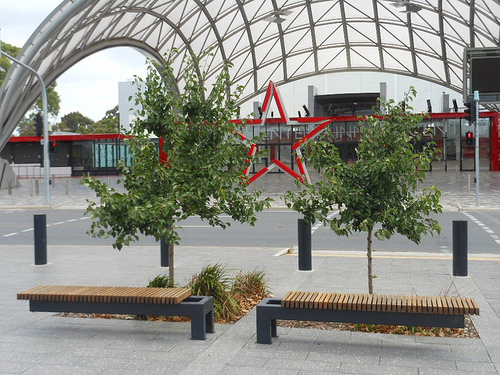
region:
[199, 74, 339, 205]
wire star in air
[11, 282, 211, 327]
bench on the ground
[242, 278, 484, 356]
bench on the ground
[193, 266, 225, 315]
grass in the flower bed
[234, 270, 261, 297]
grass in the flower bed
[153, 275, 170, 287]
grass in the flower bed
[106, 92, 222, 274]
tree in the flower bed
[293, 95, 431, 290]
tree in the flower bed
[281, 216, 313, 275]
black pole in the ground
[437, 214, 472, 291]
black pole in the ground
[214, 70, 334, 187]
The red star between the trees.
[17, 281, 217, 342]
The bench on the left.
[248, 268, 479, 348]
The bench on the right.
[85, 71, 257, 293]
The tree on the left.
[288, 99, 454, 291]
The tree on the right.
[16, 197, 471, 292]
The black poles on the sidewalk.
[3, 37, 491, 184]
The building in the background.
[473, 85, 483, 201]
The tall silver pole on the right.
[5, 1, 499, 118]
The arched design over the street.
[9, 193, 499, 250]
The street in the middle of the photo.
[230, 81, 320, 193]
red sculpture of a star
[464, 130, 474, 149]
red traffic light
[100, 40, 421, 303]
two trees with green leaves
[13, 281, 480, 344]
two benches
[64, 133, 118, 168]
walkway in the background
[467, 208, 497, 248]
white painted lines on the pavement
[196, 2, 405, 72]
a metal and glass structure overhead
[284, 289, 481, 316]
wooden slats on a bench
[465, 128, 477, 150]
do not walk signal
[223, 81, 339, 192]
large star behind the trees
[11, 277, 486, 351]
two wood and metal benches on sidewalk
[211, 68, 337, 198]
red metal star statue in front of building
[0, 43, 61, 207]
metal pole of streetlamp on sidewalk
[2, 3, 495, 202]
metal dome in front of building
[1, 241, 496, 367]
stone brick pavement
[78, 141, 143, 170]
windows on front of building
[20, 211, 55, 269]
black pole on sidewalk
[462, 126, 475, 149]
black traffic sign with red light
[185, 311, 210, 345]
metal leg of bench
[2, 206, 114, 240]
white lines drawn on street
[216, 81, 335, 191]
A red decorative star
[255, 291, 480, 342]
A blue wooden bench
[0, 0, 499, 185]
A dome with glass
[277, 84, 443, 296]
A small tree with leaves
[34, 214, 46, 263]
A black pole or post.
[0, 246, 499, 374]
A brick ground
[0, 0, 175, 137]
A sky with clouds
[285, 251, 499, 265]
A yellow line near curb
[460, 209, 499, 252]
A white broken line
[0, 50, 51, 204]
A telephone pole